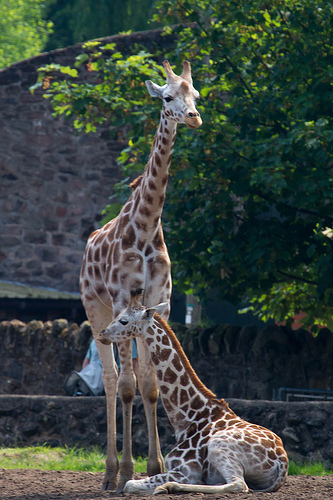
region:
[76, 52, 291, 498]
Two giraffes near each other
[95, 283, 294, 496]
A giraffe laying on the ground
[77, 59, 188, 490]
A giraffe standing on the ground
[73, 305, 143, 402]
A person behind the giraffe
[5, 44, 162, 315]
A wall of rock behind the giraffe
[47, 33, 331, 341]
A tree near the giraffe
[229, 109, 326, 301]
Leaves on a tree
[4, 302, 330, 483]
A stone fence behind the giraffe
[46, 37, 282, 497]
Two giraffes beside each other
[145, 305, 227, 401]
The mane of a giraffe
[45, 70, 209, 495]
These are giraffes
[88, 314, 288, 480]
This giraffe is resting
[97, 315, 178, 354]
The giraffe looks tired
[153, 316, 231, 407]
The giraffes mane is brown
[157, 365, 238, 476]
The giraffe is patterned brown and white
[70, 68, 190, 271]
This giraffe is standing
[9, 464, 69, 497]
The ground here is brown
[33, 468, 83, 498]
The ground here is made of dirt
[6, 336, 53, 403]
This wall is made of stone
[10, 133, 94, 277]
The wall back here is gray.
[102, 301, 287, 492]
giraffe laying on ground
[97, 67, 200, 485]
giraffe standing on ground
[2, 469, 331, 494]
black dirt on ground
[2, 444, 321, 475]
green grass on ground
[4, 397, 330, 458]
stone wall on ground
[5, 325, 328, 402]
stone wall behind giraffe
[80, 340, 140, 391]
person behind giraffe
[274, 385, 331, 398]
metal pole behind wall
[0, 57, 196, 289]
stone building behind giraffe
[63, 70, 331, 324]
green leaves of the tree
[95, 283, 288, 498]
giraffe sitting on ground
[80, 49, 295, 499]
giraffes side by side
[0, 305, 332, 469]
stone and cement wall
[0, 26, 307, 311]
arched stone wall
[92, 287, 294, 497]
young giraffe on dirt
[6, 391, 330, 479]
grass by stone wall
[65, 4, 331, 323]
branches covered with leaves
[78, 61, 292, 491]
giraffe standing over young giraffe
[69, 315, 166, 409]
person sitting on stone wall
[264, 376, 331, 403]
metal pipes by stone wall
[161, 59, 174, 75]
horn to the left of horn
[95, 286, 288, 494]
tired giraffe is sitting on the ground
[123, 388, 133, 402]
brown giraffe knees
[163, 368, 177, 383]
brown spots on giraffe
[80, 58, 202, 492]
giraffe is standing over a giraffe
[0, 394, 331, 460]
stone wall behind giraffe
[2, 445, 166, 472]
green grass next to wall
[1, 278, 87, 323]
roof of building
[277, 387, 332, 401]
metal railing behind wall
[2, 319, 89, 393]
wall behind wall